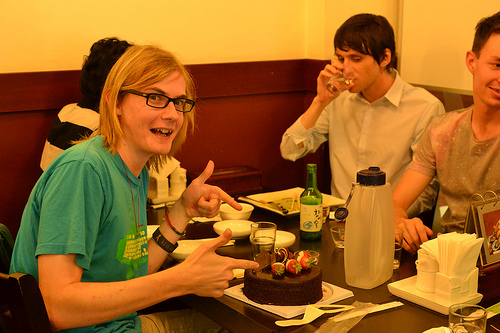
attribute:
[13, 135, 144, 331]
shirt — blue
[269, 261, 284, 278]
stem — green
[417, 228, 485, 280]
napkins — white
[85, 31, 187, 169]
hair — blonde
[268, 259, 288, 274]
strawberry — red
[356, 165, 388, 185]
cover — black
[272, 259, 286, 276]
strawberries — red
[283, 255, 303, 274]
strawberries — red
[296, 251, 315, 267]
strawberries — red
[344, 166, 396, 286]
container — plastic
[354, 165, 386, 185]
top — black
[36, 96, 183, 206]
shirt — striped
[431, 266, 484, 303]
holder — white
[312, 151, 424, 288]
jug — plastic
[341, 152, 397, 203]
lid — black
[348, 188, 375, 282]
bottle — plastic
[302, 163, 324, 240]
bottle — green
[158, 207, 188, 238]
bracelet — pink, black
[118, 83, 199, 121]
glasses — black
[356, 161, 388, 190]
cover — black